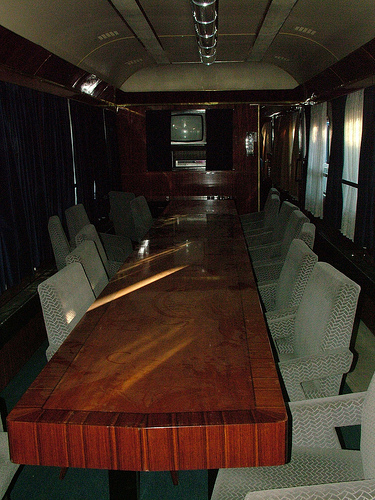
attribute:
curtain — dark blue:
[0, 78, 70, 301]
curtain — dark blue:
[67, 94, 108, 216]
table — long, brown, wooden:
[14, 171, 306, 487]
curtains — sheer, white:
[306, 107, 325, 217]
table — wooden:
[109, 178, 264, 293]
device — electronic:
[172, 157, 208, 167]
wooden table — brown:
[48, 226, 302, 474]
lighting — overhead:
[190, 0, 218, 70]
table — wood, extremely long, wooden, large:
[8, 193, 286, 469]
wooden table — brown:
[8, 188, 293, 475]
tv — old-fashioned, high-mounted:
[168, 108, 208, 146]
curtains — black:
[146, 110, 171, 168]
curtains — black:
[203, 107, 234, 170]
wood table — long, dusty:
[147, 185, 246, 296]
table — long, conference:
[108, 156, 276, 346]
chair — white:
[207, 392, 361, 499]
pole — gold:
[246, 98, 267, 218]